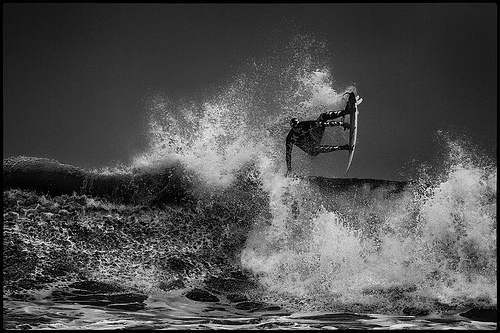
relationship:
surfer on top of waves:
[266, 94, 366, 176] [5, 146, 494, 331]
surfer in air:
[266, 94, 366, 176] [6, 5, 484, 179]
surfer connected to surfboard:
[266, 94, 366, 176] [340, 88, 368, 180]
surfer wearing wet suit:
[266, 94, 366, 176] [303, 107, 341, 167]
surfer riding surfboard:
[266, 94, 366, 176] [340, 88, 368, 180]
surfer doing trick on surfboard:
[266, 94, 366, 176] [340, 88, 368, 180]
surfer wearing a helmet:
[266, 94, 366, 176] [285, 115, 302, 130]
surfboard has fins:
[340, 88, 368, 180] [356, 93, 365, 110]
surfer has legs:
[266, 94, 366, 176] [315, 109, 350, 162]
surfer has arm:
[266, 94, 366, 176] [280, 136, 301, 180]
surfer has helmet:
[266, 94, 366, 176] [285, 115, 302, 130]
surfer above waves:
[266, 94, 366, 176] [5, 146, 494, 331]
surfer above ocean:
[266, 94, 366, 176] [9, 227, 491, 329]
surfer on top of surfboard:
[266, 94, 366, 176] [340, 88, 368, 180]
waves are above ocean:
[5, 146, 494, 331] [9, 227, 491, 329]